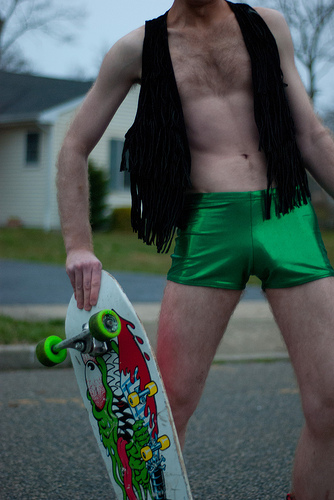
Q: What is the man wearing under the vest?
A: Nothing.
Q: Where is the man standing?
A: In the street.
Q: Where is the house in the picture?
A: Behind the man.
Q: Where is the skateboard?
A: In the man's hand.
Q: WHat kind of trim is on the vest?
A: Fringe.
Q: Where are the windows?
A: On the house.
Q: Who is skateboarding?
A: A man in a black vest.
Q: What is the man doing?
A: Riding a skateboard.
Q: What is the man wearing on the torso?
A: A vest.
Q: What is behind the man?
A: A small house.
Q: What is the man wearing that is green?
A: Shorts.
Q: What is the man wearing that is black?
A: A vest.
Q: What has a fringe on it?
A: The black vest.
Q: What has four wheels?
A: The skateboard.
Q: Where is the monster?
A: On the deck of the board.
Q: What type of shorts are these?
A: Tight green shorts.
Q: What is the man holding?
A: A skateboard.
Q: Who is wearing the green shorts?
A: The man in the picture.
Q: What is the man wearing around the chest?
A: A vest.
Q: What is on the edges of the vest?
A: Fringe.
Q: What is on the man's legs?
A: Hair.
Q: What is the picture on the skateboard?
A: A green blob skateboarding.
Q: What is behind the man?
A: A house.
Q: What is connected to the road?
A: A driveway.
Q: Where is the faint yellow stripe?
A: On the road.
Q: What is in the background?
A: House and trees.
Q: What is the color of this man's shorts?
A: Green.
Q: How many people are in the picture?
A: One.